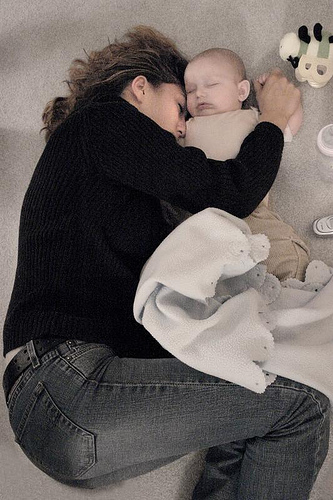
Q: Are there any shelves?
A: No, there are no shelves.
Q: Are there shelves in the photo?
A: No, there are no shelves.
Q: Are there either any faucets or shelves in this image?
A: No, there are no shelves or faucets.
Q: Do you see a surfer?
A: No, there are no surfers.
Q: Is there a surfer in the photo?
A: No, there are no surfers.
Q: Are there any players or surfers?
A: No, there are no surfers or players.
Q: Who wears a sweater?
A: The mom wears a sweater.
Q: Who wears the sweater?
A: The mom wears a sweater.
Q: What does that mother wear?
A: The mother wears a sweater.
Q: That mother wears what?
A: The mother wears a sweater.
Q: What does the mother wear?
A: The mother wears a sweater.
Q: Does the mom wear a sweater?
A: Yes, the mom wears a sweater.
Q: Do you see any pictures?
A: No, there are no pictures.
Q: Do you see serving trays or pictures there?
A: No, there are no pictures or serving trays.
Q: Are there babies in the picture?
A: Yes, there is a baby.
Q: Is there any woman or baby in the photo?
A: Yes, there is a baby.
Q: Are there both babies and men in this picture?
A: No, there is a baby but no men.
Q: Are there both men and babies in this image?
A: No, there is a baby but no men.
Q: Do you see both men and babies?
A: No, there is a baby but no men.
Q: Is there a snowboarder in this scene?
A: No, there are no snowboarders.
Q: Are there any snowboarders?
A: No, there are no snowboarders.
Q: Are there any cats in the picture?
A: No, there are no cats.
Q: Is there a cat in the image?
A: No, there are no cats.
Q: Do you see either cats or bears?
A: No, there are no cats or bears.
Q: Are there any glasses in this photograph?
A: No, there are no glasses.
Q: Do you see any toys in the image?
A: Yes, there is a toy.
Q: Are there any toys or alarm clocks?
A: Yes, there is a toy.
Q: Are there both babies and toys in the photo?
A: Yes, there are both a toy and a baby.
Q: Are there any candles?
A: No, there are no candles.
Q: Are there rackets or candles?
A: No, there are no candles or rackets.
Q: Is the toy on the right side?
A: Yes, the toy is on the right of the image.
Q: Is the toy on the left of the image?
A: No, the toy is on the right of the image.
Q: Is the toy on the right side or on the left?
A: The toy is on the right of the image.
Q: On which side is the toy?
A: The toy is on the right of the image.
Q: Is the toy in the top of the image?
A: Yes, the toy is in the top of the image.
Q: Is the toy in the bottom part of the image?
A: No, the toy is in the top of the image.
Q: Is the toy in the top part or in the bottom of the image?
A: The toy is in the top of the image.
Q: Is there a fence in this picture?
A: No, there are no fences.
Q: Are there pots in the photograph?
A: No, there are no pots.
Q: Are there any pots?
A: No, there are no pots.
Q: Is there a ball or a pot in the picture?
A: No, there are no pots or balls.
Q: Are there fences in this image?
A: No, there are no fences.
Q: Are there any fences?
A: No, there are no fences.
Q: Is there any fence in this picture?
A: No, there are no fences.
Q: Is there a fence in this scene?
A: No, there are no fences.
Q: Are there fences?
A: No, there are no fences.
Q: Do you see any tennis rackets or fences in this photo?
A: No, there are no fences or tennis rackets.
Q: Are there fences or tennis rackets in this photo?
A: No, there are no fences or tennis rackets.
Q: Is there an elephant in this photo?
A: No, there are no elephants.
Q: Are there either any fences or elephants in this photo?
A: No, there are no elephants or fences.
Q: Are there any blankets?
A: Yes, there is a blanket.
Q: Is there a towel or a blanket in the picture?
A: Yes, there is a blanket.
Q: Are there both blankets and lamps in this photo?
A: No, there is a blanket but no lamps.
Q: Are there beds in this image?
A: No, there are no beds.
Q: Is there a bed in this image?
A: No, there are no beds.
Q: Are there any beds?
A: No, there are no beds.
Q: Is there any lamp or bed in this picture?
A: No, there are no beds or lamps.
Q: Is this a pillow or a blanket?
A: This is a blanket.